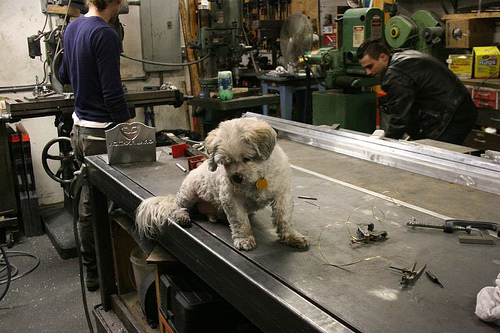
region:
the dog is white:
[196, 124, 288, 193]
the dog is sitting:
[173, 114, 287, 220]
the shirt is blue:
[81, 39, 103, 91]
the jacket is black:
[399, 64, 436, 109]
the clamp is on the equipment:
[405, 206, 498, 244]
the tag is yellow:
[253, 172, 272, 194]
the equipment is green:
[326, 57, 346, 108]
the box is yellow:
[472, 43, 498, 85]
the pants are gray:
[70, 127, 97, 154]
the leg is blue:
[274, 85, 292, 121]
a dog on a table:
[129, 114, 345, 300]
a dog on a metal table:
[125, 110, 403, 300]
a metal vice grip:
[402, 208, 498, 257]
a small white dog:
[131, 115, 311, 252]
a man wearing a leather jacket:
[358, 35, 480, 147]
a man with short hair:
[350, 38, 391, 78]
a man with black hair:
[354, 32, 394, 82]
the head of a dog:
[198, 112, 278, 186]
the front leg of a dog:
[271, 197, 314, 251]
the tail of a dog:
[132, 189, 178, 245]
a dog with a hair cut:
[202, 123, 303, 242]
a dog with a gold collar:
[208, 130, 295, 205]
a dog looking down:
[204, 121, 296, 248]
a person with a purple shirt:
[61, 4, 131, 120]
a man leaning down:
[351, 33, 473, 135]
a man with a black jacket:
[354, 36, 469, 131]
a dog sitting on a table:
[159, 116, 324, 264]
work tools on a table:
[339, 184, 475, 314]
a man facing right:
[69, 2, 147, 129]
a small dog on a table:
[92, 115, 442, 321]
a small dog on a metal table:
[130, 117, 445, 282]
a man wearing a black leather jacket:
[353, 33, 480, 152]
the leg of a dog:
[223, 205, 259, 252]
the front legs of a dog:
[226, 200, 312, 254]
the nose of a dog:
[231, 171, 244, 183]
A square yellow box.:
[469, 44, 499, 80]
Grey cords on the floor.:
[1, 244, 42, 302]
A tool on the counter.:
[406, 209, 498, 239]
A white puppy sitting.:
[135, 114, 317, 253]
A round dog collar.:
[249, 169, 270, 192]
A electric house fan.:
[273, 13, 317, 79]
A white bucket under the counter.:
[126, 246, 157, 309]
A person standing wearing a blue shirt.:
[59, 0, 136, 292]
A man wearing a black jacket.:
[354, 38, 482, 152]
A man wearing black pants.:
[354, 38, 477, 148]